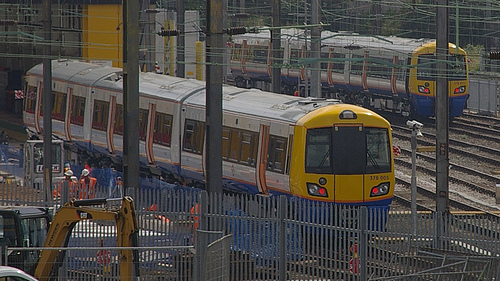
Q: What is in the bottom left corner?
A: Bulldozer.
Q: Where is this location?
A: Train yard.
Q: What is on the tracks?
A: Trains.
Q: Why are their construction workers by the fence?
A: Construction.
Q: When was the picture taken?
A: Daytime.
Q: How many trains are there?
A: Two.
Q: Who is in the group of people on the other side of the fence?
A: Construction workers.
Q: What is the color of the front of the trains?
A: Yellow.